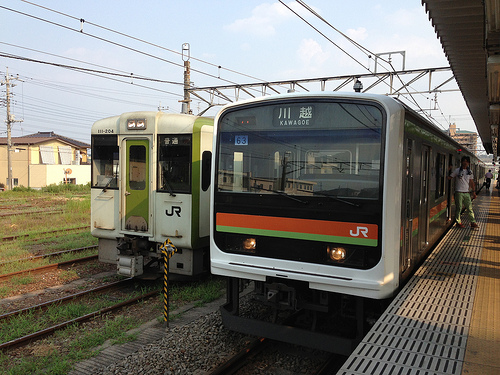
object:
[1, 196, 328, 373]
ground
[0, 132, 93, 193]
building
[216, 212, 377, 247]
stripe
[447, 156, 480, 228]
man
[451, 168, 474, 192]
t-shirt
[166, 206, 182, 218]
logo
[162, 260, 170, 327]
pole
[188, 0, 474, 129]
cloud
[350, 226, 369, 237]
logo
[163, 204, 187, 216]
logo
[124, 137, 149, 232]
door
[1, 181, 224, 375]
grass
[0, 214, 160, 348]
tracks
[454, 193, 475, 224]
pants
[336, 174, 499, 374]
platform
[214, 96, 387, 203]
window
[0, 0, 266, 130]
line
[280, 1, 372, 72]
line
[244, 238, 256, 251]
head light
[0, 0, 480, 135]
sky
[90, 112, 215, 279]
train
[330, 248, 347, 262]
headlight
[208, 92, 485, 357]
train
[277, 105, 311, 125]
sign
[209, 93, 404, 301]
front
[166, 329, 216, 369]
gravel